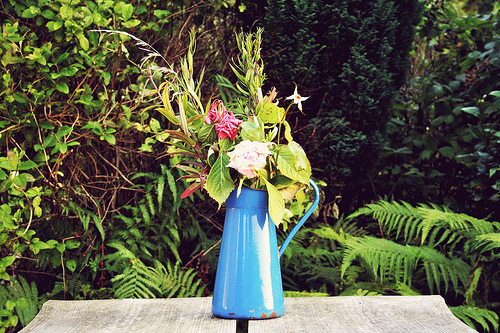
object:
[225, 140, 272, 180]
pink peony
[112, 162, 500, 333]
fern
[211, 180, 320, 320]
can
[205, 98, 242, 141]
flower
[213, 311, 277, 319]
spots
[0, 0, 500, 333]
greenery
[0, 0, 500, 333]
trees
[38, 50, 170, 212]
vines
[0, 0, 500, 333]
outdoors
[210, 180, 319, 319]
vase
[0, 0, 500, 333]
plant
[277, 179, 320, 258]
handle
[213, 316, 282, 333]
base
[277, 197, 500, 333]
frond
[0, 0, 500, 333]
bush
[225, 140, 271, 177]
flowers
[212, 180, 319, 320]
pitcher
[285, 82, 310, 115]
flower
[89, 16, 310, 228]
still life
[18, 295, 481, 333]
floor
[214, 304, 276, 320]
rust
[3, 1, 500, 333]
foliage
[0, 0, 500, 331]
garden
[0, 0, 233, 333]
wild bush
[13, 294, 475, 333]
table